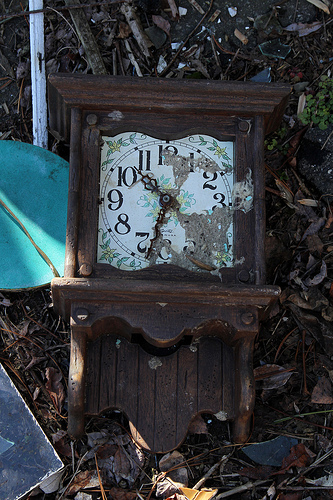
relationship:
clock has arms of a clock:
[45, 68, 294, 456] [130, 161, 166, 209]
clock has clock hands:
[45, 68, 294, 456] [144, 198, 170, 258]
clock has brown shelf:
[45, 68, 294, 456] [47, 73, 288, 453]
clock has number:
[45, 68, 294, 456] [135, 147, 151, 173]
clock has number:
[45, 68, 294, 456] [106, 186, 123, 211]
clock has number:
[45, 68, 294, 456] [111, 212, 129, 238]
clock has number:
[45, 68, 294, 456] [133, 232, 151, 253]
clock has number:
[45, 68, 294, 456] [156, 144, 175, 168]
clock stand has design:
[45, 71, 293, 453] [68, 397, 249, 452]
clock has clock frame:
[45, 68, 294, 456] [44, 69, 292, 454]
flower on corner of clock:
[213, 144, 226, 157] [45, 68, 294, 456]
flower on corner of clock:
[107, 136, 120, 152] [45, 68, 294, 456]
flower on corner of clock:
[101, 243, 117, 256] [45, 68, 294, 456]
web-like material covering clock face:
[95, 128, 243, 271] [100, 130, 234, 274]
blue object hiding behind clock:
[1, 139, 69, 292] [45, 68, 294, 456]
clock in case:
[45, 68, 294, 456] [44, 68, 289, 453]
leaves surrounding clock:
[1, 349, 332, 497] [45, 68, 294, 456]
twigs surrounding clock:
[0, 307, 332, 495] [45, 68, 294, 456]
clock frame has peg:
[44, 69, 292, 454] [74, 307, 89, 319]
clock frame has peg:
[44, 69, 292, 454] [239, 308, 255, 324]